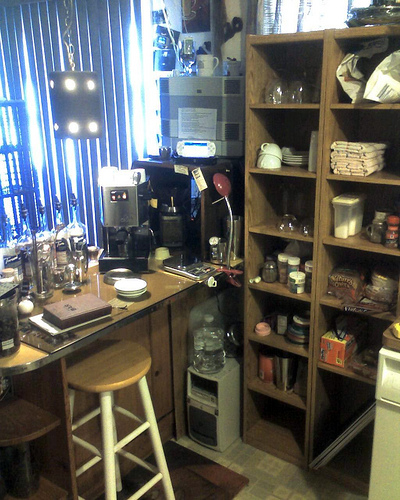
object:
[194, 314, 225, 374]
water bottle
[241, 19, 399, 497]
shelf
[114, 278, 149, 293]
plates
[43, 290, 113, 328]
book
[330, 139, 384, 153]
towels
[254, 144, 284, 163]
cups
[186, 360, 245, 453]
pc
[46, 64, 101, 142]
lamp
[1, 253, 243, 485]
desk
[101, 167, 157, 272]
machine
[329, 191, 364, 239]
container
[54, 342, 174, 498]
stool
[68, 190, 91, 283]
bottle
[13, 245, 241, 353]
counter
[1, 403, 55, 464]
shelf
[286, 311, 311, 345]
bowls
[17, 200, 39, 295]
bottles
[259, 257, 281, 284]
spices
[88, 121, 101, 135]
holes